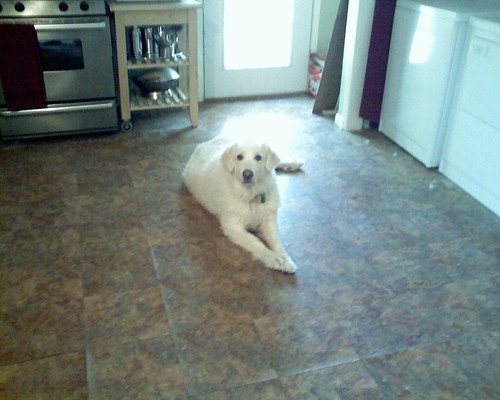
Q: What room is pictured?
A: It is a kitchen.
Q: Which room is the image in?
A: It is at the kitchen.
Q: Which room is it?
A: It is a kitchen.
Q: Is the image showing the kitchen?
A: Yes, it is showing the kitchen.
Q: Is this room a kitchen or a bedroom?
A: It is a kitchen.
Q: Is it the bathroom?
A: No, it is the kitchen.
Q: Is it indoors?
A: Yes, it is indoors.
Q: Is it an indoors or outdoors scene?
A: It is indoors.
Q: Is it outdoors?
A: No, it is indoors.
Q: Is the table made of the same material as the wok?
A: No, the table is made of wood and the wok is made of metal.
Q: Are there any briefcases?
A: No, there are no briefcases.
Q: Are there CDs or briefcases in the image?
A: No, there are no briefcases or cds.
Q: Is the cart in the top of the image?
A: Yes, the cart is in the top of the image.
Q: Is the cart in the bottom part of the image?
A: No, the cart is in the top of the image.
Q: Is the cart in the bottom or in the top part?
A: The cart is in the top of the image.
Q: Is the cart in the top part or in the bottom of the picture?
A: The cart is in the top of the image.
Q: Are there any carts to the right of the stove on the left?
A: Yes, there is a cart to the right of the stove.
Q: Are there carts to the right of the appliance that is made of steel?
A: Yes, there is a cart to the right of the stove.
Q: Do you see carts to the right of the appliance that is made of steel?
A: Yes, there is a cart to the right of the stove.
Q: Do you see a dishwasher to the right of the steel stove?
A: No, there is a cart to the right of the stove.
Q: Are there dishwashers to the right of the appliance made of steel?
A: No, there is a cart to the right of the stove.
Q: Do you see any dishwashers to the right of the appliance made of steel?
A: No, there is a cart to the right of the stove.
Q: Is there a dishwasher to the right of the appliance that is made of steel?
A: No, there is a cart to the right of the stove.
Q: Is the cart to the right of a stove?
A: Yes, the cart is to the right of a stove.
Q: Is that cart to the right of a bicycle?
A: No, the cart is to the right of a stove.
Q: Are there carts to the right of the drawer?
A: Yes, there is a cart to the right of the drawer.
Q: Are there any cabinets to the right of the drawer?
A: No, there is a cart to the right of the drawer.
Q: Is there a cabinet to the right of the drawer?
A: No, there is a cart to the right of the drawer.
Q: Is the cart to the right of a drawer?
A: Yes, the cart is to the right of a drawer.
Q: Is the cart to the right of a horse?
A: No, the cart is to the right of a drawer.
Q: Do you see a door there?
A: Yes, there is a door.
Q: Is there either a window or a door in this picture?
A: Yes, there is a door.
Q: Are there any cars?
A: No, there are no cars.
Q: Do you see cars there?
A: No, there are no cars.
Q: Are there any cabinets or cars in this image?
A: No, there are no cars or cabinets.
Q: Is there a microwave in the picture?
A: No, there are no microwaves.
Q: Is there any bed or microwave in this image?
A: No, there are no microwaves or beds.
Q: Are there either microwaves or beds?
A: No, there are no microwaves or beds.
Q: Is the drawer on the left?
A: Yes, the drawer is on the left of the image.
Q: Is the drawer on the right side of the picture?
A: No, the drawer is on the left of the image.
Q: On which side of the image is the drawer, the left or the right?
A: The drawer is on the left of the image.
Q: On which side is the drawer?
A: The drawer is on the left of the image.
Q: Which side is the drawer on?
A: The drawer is on the left of the image.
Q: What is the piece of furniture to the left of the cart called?
A: The piece of furniture is a drawer.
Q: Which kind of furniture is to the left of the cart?
A: The piece of furniture is a drawer.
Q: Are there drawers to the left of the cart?
A: Yes, there is a drawer to the left of the cart.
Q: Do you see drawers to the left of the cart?
A: Yes, there is a drawer to the left of the cart.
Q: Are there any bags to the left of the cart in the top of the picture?
A: No, there is a drawer to the left of the cart.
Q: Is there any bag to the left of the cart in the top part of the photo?
A: No, there is a drawer to the left of the cart.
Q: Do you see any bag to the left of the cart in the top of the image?
A: No, there is a drawer to the left of the cart.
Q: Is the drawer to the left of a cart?
A: Yes, the drawer is to the left of a cart.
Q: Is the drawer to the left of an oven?
A: No, the drawer is to the left of a cart.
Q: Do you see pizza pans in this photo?
A: No, there are no pizza pans.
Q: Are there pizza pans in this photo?
A: No, there are no pizza pans.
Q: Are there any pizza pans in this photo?
A: No, there are no pizza pans.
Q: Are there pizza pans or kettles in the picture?
A: No, there are no pizza pans or kettles.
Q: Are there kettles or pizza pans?
A: No, there are no pizza pans or kettles.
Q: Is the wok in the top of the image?
A: Yes, the wok is in the top of the image.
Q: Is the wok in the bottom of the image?
A: No, the wok is in the top of the image.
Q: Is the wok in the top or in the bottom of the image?
A: The wok is in the top of the image.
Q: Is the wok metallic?
A: Yes, the wok is metallic.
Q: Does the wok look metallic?
A: Yes, the wok is metallic.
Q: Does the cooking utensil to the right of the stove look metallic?
A: Yes, the wok is metallic.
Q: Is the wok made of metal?
A: Yes, the wok is made of metal.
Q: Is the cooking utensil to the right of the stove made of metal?
A: Yes, the wok is made of metal.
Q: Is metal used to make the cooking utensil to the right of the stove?
A: Yes, the wok is made of metal.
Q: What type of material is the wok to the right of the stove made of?
A: The wok is made of metal.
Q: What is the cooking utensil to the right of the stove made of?
A: The wok is made of metal.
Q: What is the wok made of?
A: The wok is made of metal.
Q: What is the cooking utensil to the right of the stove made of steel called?
A: The cooking utensil is a wok.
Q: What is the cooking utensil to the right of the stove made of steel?
A: The cooking utensil is a wok.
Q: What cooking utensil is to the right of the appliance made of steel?
A: The cooking utensil is a wok.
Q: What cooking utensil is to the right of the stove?
A: The cooking utensil is a wok.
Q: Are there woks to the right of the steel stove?
A: Yes, there is a wok to the right of the stove.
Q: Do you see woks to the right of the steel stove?
A: Yes, there is a wok to the right of the stove.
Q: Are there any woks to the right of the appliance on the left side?
A: Yes, there is a wok to the right of the stove.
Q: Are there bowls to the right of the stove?
A: No, there is a wok to the right of the stove.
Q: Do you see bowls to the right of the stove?
A: No, there is a wok to the right of the stove.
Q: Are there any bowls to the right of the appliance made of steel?
A: No, there is a wok to the right of the stove.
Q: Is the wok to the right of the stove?
A: Yes, the wok is to the right of the stove.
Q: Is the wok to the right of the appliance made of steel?
A: Yes, the wok is to the right of the stove.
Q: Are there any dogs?
A: Yes, there is a dog.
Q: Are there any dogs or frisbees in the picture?
A: Yes, there is a dog.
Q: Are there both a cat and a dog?
A: No, there is a dog but no cats.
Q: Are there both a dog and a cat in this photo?
A: No, there is a dog but no cats.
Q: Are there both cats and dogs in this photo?
A: No, there is a dog but no cats.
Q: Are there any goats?
A: No, there are no goats.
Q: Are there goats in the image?
A: No, there are no goats.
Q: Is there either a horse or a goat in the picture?
A: No, there are no goats or horses.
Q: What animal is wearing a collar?
A: The dog is wearing a collar.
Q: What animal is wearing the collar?
A: The dog is wearing a collar.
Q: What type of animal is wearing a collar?
A: The animal is a dog.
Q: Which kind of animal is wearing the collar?
A: The animal is a dog.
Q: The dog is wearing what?
A: The dog is wearing a collar.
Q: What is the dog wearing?
A: The dog is wearing a collar.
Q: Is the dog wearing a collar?
A: Yes, the dog is wearing a collar.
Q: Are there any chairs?
A: No, there are no chairs.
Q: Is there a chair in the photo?
A: No, there are no chairs.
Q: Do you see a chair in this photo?
A: No, there are no chairs.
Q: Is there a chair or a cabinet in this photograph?
A: No, there are no chairs or cabinets.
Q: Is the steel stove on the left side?
A: Yes, the stove is on the left of the image.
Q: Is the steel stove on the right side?
A: No, the stove is on the left of the image.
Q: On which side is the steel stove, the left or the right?
A: The stove is on the left of the image.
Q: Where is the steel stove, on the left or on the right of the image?
A: The stove is on the left of the image.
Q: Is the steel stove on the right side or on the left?
A: The stove is on the left of the image.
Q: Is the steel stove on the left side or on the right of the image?
A: The stove is on the left of the image.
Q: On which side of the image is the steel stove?
A: The stove is on the left of the image.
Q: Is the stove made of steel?
A: Yes, the stove is made of steel.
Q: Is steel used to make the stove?
A: Yes, the stove is made of steel.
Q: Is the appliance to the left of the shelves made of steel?
A: Yes, the stove is made of steel.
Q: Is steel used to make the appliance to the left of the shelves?
A: Yes, the stove is made of steel.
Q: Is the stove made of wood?
A: No, the stove is made of steel.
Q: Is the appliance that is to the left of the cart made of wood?
A: No, the stove is made of steel.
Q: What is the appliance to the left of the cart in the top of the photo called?
A: The appliance is a stove.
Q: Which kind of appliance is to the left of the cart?
A: The appliance is a stove.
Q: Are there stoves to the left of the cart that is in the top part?
A: Yes, there is a stove to the left of the cart.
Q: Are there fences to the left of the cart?
A: No, there is a stove to the left of the cart.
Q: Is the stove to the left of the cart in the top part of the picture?
A: Yes, the stove is to the left of the cart.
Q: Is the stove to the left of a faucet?
A: No, the stove is to the left of the cart.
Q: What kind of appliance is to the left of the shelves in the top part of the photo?
A: The appliance is a stove.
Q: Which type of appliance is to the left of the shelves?
A: The appliance is a stove.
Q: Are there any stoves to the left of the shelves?
A: Yes, there is a stove to the left of the shelves.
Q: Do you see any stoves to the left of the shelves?
A: Yes, there is a stove to the left of the shelves.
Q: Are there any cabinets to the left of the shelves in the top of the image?
A: No, there is a stove to the left of the shelves.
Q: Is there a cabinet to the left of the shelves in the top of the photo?
A: No, there is a stove to the left of the shelves.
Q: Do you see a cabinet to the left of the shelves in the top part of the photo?
A: No, there is a stove to the left of the shelves.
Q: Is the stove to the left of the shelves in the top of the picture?
A: Yes, the stove is to the left of the shelves.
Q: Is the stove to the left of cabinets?
A: No, the stove is to the left of the shelves.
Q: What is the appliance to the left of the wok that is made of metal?
A: The appliance is a stove.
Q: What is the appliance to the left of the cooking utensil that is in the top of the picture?
A: The appliance is a stove.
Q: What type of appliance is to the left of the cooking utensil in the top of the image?
A: The appliance is a stove.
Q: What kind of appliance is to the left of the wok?
A: The appliance is a stove.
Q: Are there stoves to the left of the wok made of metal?
A: Yes, there is a stove to the left of the wok.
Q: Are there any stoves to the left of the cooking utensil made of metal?
A: Yes, there is a stove to the left of the wok.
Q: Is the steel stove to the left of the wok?
A: Yes, the stove is to the left of the wok.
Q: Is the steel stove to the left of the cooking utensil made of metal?
A: Yes, the stove is to the left of the wok.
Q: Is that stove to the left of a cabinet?
A: No, the stove is to the left of the wok.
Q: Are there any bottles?
A: No, there are no bottles.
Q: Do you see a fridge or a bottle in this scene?
A: No, there are no bottles or refrigerators.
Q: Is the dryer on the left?
A: No, the dryer is on the right of the image.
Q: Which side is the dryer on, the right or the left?
A: The dryer is on the right of the image.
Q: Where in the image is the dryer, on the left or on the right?
A: The dryer is on the right of the image.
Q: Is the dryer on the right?
A: Yes, the dryer is on the right of the image.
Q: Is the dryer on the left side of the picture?
A: No, the dryer is on the right of the image.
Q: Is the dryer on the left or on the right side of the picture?
A: The dryer is on the right of the image.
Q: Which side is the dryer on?
A: The dryer is on the right of the image.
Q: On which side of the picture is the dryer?
A: The dryer is on the right of the image.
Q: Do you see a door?
A: Yes, there is a door.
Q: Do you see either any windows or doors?
A: Yes, there is a door.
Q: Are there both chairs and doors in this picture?
A: No, there is a door but no chairs.